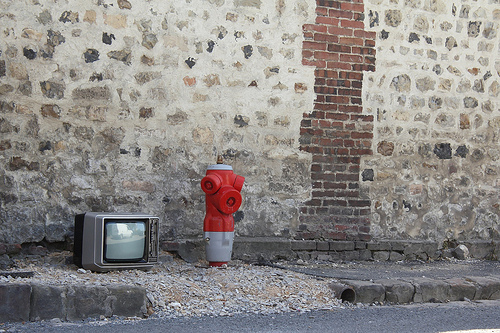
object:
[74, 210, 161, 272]
television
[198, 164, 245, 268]
hydrant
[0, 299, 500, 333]
road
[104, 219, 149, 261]
screen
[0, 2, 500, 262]
wall